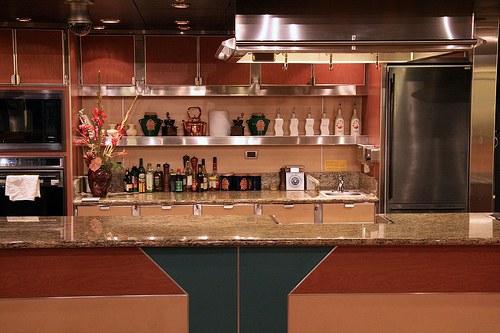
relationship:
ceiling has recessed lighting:
[1, 1, 499, 37] [16, 1, 192, 32]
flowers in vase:
[75, 70, 139, 174] [86, 165, 112, 198]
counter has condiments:
[74, 170, 380, 204] [124, 152, 287, 191]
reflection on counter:
[79, 186, 381, 203] [74, 170, 380, 204]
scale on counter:
[284, 165, 307, 191] [74, 170, 380, 204]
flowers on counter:
[75, 70, 139, 174] [74, 170, 380, 204]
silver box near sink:
[356, 142, 373, 167] [323, 190, 363, 199]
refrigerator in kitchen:
[380, 58, 470, 214] [0, 0, 499, 333]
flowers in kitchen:
[75, 70, 139, 174] [0, 0, 499, 333]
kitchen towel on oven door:
[5, 176, 42, 202] [0, 170, 68, 217]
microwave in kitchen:
[0, 89, 66, 152] [0, 0, 499, 333]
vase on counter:
[86, 165, 112, 198] [74, 170, 380, 204]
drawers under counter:
[75, 201, 376, 224] [74, 170, 380, 204]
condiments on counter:
[124, 152, 287, 191] [74, 170, 380, 204]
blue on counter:
[138, 246, 338, 332] [0, 213, 499, 331]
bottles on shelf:
[265, 102, 372, 141] [80, 129, 373, 155]